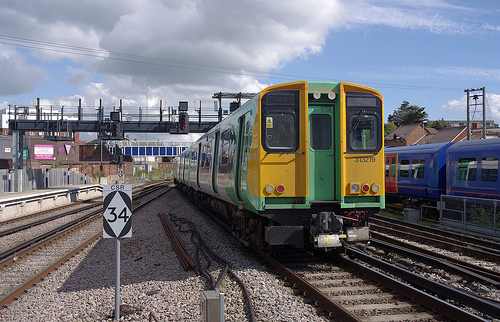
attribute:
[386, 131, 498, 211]
train — red, blue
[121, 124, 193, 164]
building — white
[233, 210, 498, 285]
tracks — black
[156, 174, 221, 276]
platform — concrete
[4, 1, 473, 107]
clouds — patchy, white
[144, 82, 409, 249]
train — green, yellow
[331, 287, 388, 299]
train track — wooden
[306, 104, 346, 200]
door — Green 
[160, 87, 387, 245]
train — Green and yellow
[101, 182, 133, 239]
sign — Black and white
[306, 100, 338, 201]
door — green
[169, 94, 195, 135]
traffic light — black , red light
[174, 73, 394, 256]
train — yellow , green